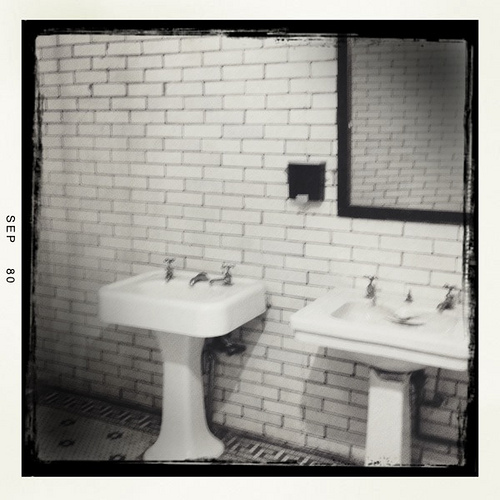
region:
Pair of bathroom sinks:
[97, 253, 462, 465]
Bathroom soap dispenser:
[285, 158, 329, 210]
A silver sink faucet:
[154, 252, 237, 292]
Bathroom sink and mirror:
[290, 40, 461, 465]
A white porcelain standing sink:
[93, 255, 260, 462]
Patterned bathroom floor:
[40, 375, 326, 472]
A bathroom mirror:
[331, 36, 459, 228]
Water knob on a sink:
[206, 261, 235, 289]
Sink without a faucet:
[306, 273, 459, 468]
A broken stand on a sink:
[356, 366, 419, 466]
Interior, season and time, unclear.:
[24, 19, 479, 476]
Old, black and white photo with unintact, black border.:
[24, 23, 493, 485]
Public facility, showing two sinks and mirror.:
[37, 24, 465, 469]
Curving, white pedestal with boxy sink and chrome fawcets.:
[106, 255, 262, 458]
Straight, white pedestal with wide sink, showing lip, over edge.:
[297, 267, 464, 453]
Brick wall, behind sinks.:
[48, 116, 188, 219]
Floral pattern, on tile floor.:
[58, 417, 125, 459]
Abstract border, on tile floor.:
[83, 387, 150, 434]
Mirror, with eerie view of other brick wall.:
[323, 42, 468, 231]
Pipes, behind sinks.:
[210, 341, 452, 439]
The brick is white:
[223, 386, 264, 411]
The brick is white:
[260, 393, 305, 420]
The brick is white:
[301, 405, 353, 430]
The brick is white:
[326, 423, 365, 445]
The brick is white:
[278, 416, 326, 439]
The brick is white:
[238, 403, 280, 427]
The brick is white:
[208, 399, 244, 417]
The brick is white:
[223, 408, 266, 438]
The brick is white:
[261, 418, 310, 448]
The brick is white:
[305, 429, 350, 461]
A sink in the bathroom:
[100, 256, 265, 461]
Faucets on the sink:
[166, 257, 233, 284]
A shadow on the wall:
[302, 349, 364, 444]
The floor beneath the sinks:
[35, 379, 354, 465]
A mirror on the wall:
[349, 37, 471, 212]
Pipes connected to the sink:
[206, 339, 243, 422]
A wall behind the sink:
[36, 36, 470, 463]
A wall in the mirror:
[350, 37, 467, 211]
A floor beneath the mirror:
[38, 382, 355, 464]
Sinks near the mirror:
[96, 259, 468, 464]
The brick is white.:
[54, 55, 94, 73]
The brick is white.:
[90, 52, 128, 73]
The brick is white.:
[61, 182, 99, 202]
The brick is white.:
[93, 183, 134, 203]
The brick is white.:
[127, 185, 170, 206]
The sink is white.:
[89, 250, 273, 467]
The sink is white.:
[287, 269, 467, 463]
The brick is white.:
[164, 213, 206, 234]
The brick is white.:
[201, 218, 247, 239]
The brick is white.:
[241, 222, 287, 242]